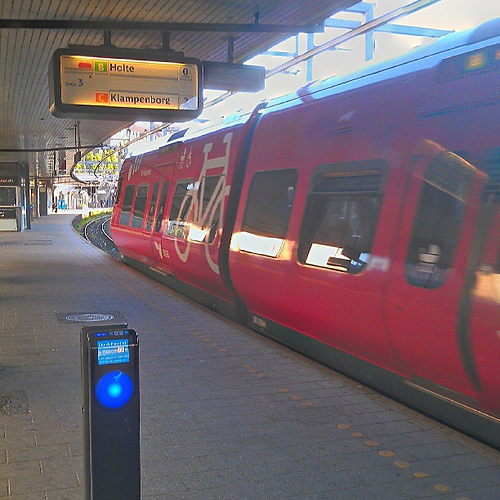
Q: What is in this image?
A: A train.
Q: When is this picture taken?
A: During the day.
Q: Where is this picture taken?
A: Train station.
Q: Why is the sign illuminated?
A: To display the name of the stop.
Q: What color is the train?
A: Red.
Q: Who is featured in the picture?
A: The train.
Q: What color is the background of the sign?
A: White.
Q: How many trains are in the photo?
A: One.